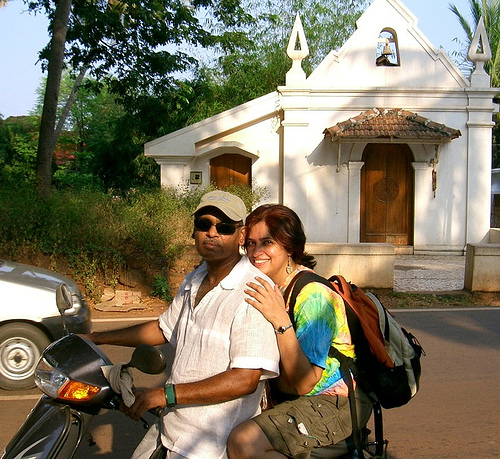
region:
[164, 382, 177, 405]
A greenish wrist band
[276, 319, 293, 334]
A thin wrist watch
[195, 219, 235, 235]
Dark shades covering the eyes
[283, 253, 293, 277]
An earring hanging down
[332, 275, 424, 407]
A back back hanging on the woman's back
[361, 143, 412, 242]
A brown door with a decoration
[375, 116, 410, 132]
Old brown roof tiles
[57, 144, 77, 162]
A partly visible roof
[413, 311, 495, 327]
Shadow on the street cast by the sun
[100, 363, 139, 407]
A piece of cloth around the dide mirror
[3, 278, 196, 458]
A silver scooter.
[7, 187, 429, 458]
A man and a woman on a scooter.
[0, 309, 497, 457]
The road.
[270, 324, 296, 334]
A small wristwatch.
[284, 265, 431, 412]
A black, orange, and beige book bag.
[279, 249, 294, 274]
A long pair of earrings.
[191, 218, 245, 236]
A black pair of sunglasses.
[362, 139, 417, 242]
A wooden front door.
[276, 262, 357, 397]
A tie-dyed shirt.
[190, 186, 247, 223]
A light brown colored ball cap.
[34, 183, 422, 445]
two people on riding moped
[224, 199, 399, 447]
woman wearing tie dye shirt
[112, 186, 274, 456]
man wearing white shirt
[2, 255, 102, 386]
front end of silver car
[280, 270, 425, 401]
backpack of woman riding moped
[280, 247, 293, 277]
earring of woman riding moped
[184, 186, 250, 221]
biege hat of man riding moped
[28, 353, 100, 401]
front lights of moped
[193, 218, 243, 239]
sunglasses of man riding moped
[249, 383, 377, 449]
khaki shorts of woman riding moped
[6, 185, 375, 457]
a man and a woman on a motorcycle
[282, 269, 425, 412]
woman with a backpack on her shoulders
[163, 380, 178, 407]
man wearing a green bracelet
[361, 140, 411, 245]
a church's wooden door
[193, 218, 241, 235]
man wearing black sunglasses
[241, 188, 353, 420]
woman holding a man's shoulders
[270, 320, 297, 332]
woman wearing a silver watch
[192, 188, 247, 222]
man wearing a gray cap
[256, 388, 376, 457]
woman wearing khaki shorts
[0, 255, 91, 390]
a silvery cap on a street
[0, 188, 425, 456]
two people on a scooter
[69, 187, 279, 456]
man wearing a hat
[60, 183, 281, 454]
man wearing sunglasses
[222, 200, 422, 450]
woman wearing a backback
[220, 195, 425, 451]
woman wearing cargo shorts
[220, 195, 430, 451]
woman wearing a tie-dye shirt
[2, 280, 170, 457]
scooter has orange and white headlights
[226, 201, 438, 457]
woman smiling at camera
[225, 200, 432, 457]
woman riding on back of scooter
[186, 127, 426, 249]
building has two wooden doors